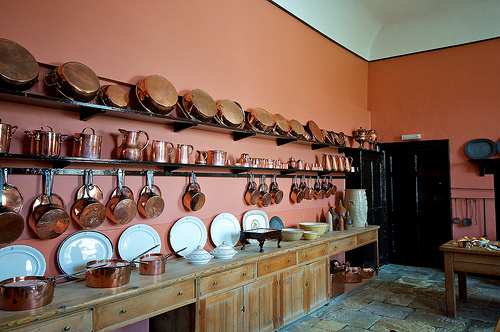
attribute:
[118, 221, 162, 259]
plate — round, white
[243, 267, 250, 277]
handle — metal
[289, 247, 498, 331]
floor — rock, stone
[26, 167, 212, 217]
pans — copper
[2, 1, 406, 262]
wall — orange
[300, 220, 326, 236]
bowl — white, yellow, brown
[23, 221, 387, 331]
table — wood, long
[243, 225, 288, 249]
tray — small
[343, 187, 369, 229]
jug — white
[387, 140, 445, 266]
door — open, black, brown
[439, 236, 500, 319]
table — brown, small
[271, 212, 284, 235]
plate — blue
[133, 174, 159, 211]
pot — copper, brass, hanging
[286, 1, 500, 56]
ceiling — arched